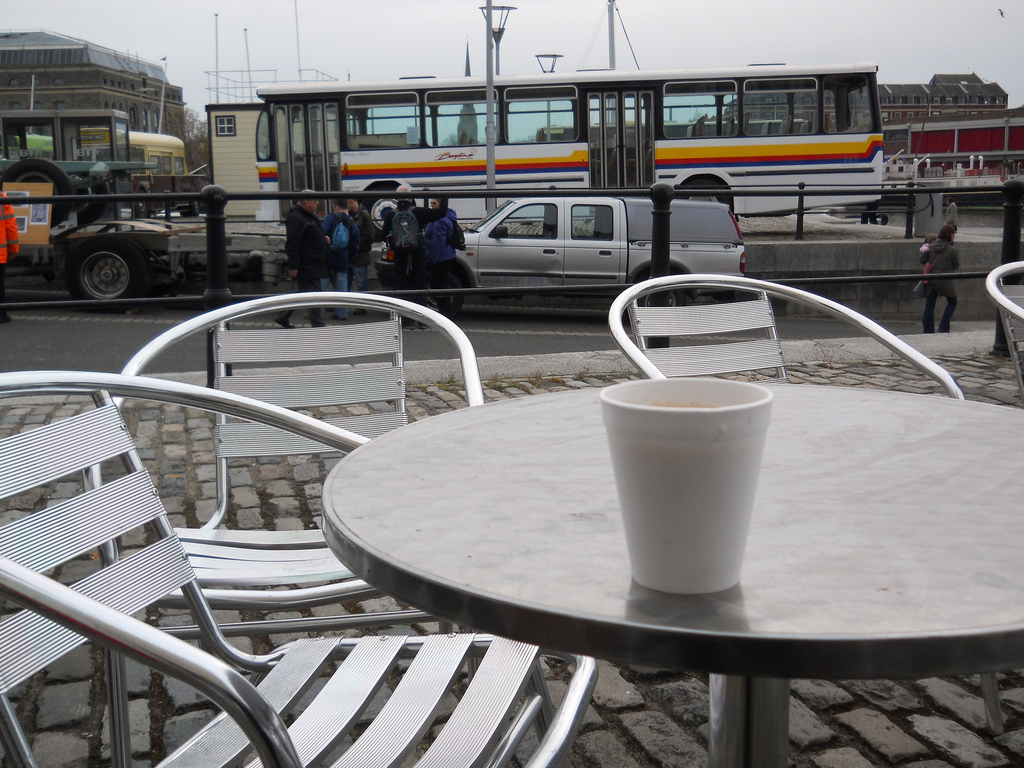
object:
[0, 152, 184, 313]
car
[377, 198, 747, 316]
truck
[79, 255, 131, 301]
tire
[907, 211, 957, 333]
person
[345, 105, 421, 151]
window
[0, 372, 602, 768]
chair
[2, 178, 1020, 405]
fence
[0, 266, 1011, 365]
road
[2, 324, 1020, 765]
terrace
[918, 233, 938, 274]
baby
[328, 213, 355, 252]
backpack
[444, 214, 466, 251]
purse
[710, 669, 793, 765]
post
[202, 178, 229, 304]
post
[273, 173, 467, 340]
people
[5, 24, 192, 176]
building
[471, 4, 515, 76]
street lamp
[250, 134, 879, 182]
lines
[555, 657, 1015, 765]
sidewalk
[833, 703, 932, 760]
brick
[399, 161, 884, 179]
stripe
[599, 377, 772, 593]
cup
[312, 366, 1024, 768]
table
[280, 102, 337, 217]
door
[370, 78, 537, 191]
rail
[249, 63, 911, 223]
bus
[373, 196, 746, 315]
car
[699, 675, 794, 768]
leg